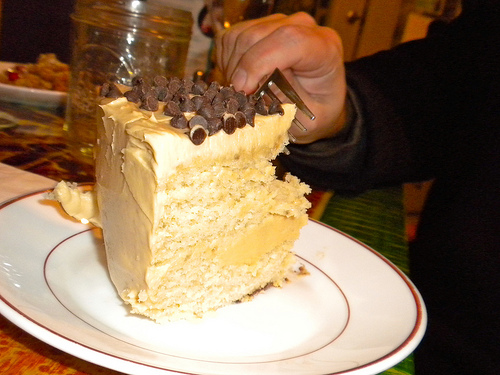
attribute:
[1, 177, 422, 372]
plate — white , dark red ringed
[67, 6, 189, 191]
jar — empty 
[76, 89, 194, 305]
icing — yellow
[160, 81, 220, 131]
chips — chocolate, sideways, upside down, upright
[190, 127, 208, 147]
chip — chocolate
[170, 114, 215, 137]
chip — chocolate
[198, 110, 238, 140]
chip — chocolate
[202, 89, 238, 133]
chip — chocolate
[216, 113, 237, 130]
chip — chocolate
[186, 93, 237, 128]
chip — chocolate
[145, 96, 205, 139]
chip — chocolate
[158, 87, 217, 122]
chip — chocolate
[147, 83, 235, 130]
chip — chocolate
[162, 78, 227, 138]
chip — chocolate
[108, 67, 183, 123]
pieces — chocolate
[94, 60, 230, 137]
pieces — chocolate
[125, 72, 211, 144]
pieces — chocolate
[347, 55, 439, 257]
black — coat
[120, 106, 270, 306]
cake — a slice, triangular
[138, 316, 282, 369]
plate — white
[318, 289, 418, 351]
boarder — red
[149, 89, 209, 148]
chips — chocolate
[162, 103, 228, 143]
chips — chocolate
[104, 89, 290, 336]
cake — cheese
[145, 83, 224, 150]
kisses — hershey